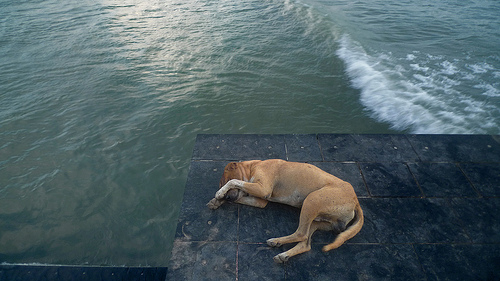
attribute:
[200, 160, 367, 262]
dog — blonde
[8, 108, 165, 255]
water — calm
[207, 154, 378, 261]
dog — beige, lying down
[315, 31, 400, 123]
ocean waves — white, green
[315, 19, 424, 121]
ocean waves — green, white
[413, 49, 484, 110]
ocean waves — white, green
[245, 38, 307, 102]
ocean waves — green, white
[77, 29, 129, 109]
ocean waves — white, green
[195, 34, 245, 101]
ocean waves — green, white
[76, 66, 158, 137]
ocean waves — white, green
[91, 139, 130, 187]
ocean waves — green, white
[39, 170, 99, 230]
ocean waves — white, green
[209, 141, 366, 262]
dog — lying down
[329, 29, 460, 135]
water — white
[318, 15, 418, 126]
wave — small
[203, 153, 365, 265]
dog — brown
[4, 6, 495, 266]
water — calm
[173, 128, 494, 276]
stone — black